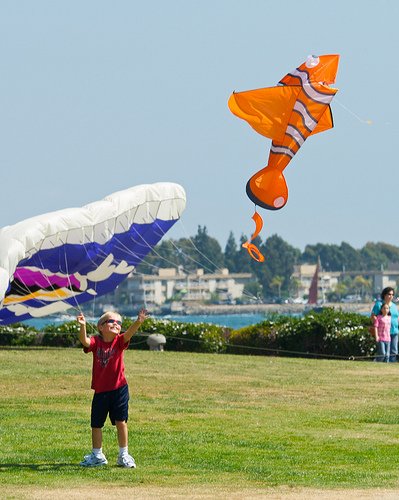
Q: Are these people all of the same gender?
A: No, they are both male and female.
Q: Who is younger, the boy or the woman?
A: The boy is younger than the woman.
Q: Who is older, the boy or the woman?
A: The woman is older than the boy.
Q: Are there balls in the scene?
A: No, there are no balls.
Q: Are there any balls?
A: No, there are no balls.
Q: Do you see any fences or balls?
A: No, there are no balls or fences.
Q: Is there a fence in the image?
A: No, there are no fences.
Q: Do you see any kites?
A: Yes, there is a kite.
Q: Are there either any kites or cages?
A: Yes, there is a kite.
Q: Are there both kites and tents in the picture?
A: No, there is a kite but no tents.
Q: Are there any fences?
A: No, there are no fences.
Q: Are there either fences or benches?
A: No, there are no fences or benches.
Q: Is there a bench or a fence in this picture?
A: No, there are no fences or benches.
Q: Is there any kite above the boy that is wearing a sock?
A: Yes, there is a kite above the boy.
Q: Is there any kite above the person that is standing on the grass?
A: Yes, there is a kite above the boy.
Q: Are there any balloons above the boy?
A: No, there is a kite above the boy.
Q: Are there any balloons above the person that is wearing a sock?
A: No, there is a kite above the boy.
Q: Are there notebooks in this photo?
A: No, there are no notebooks.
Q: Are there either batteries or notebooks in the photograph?
A: No, there are no notebooks or batteries.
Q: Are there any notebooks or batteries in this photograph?
A: No, there are no notebooks or batteries.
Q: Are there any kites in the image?
A: Yes, there is a kite.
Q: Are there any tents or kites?
A: Yes, there is a kite.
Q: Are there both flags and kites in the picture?
A: No, there is a kite but no flags.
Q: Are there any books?
A: No, there are no books.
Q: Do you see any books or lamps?
A: No, there are no books or lamps.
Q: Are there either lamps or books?
A: No, there are no books or lamps.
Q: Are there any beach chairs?
A: No, there are no beach chairs.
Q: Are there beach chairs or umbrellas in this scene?
A: No, there are no beach chairs or umbrellas.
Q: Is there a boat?
A: Yes, there is a boat.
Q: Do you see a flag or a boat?
A: Yes, there is a boat.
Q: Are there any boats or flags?
A: Yes, there is a boat.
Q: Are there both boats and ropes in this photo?
A: No, there is a boat but no ropes.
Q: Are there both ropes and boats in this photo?
A: No, there is a boat but no ropes.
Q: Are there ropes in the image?
A: No, there are no ropes.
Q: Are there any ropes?
A: No, there are no ropes.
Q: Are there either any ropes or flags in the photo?
A: No, there are no ropes or flags.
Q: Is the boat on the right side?
A: Yes, the boat is on the right of the image.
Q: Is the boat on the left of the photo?
A: No, the boat is on the right of the image.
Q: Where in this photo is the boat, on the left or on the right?
A: The boat is on the right of the image.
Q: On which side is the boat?
A: The boat is on the right of the image.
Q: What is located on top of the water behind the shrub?
A: The boat is on top of the water.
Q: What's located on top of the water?
A: The boat is on top of the water.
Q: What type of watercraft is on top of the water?
A: The watercraft is a boat.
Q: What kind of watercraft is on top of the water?
A: The watercraft is a boat.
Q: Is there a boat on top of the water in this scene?
A: Yes, there is a boat on top of the water.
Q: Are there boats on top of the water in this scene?
A: Yes, there is a boat on top of the water.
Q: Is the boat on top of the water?
A: Yes, the boat is on top of the water.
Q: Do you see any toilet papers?
A: No, there are no toilet papers.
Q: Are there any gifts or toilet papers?
A: No, there are no toilet papers or gifts.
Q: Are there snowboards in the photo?
A: No, there are no snowboards.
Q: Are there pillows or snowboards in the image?
A: No, there are no snowboards or pillows.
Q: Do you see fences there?
A: No, there are no fences.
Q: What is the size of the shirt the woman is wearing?
A: The shirt is large.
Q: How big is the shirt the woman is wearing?
A: The shirt is large.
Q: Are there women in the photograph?
A: Yes, there is a woman.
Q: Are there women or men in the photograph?
A: Yes, there is a woman.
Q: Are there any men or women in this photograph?
A: Yes, there is a woman.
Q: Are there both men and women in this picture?
A: No, there is a woman but no men.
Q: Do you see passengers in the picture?
A: No, there are no passengers.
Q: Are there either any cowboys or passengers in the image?
A: No, there are no passengers or cowboys.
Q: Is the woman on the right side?
A: Yes, the woman is on the right of the image.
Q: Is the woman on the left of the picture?
A: No, the woman is on the right of the image.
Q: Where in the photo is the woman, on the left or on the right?
A: The woman is on the right of the image.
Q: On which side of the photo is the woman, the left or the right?
A: The woman is on the right of the image.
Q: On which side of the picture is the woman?
A: The woman is on the right of the image.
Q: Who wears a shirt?
A: The woman wears a shirt.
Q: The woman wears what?
A: The woman wears a shirt.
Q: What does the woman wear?
A: The woman wears a shirt.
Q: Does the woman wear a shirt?
A: Yes, the woman wears a shirt.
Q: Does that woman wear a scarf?
A: No, the woman wears a shirt.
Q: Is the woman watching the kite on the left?
A: Yes, the woman is watching the kite.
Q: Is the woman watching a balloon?
A: No, the woman is watching the kite.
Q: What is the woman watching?
A: The woman is watching the kite.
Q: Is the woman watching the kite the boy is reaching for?
A: Yes, the woman is watching the kite.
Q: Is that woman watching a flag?
A: No, the woman is watching the kite.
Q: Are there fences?
A: No, there are no fences.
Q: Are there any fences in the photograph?
A: No, there are no fences.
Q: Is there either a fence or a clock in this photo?
A: No, there are no fences or clocks.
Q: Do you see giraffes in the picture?
A: No, there are no giraffes.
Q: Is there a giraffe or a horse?
A: No, there are no giraffes or horses.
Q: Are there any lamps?
A: No, there are no lamps.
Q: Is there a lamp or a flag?
A: No, there are no lamps or flags.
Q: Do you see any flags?
A: No, there are no flags.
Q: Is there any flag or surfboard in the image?
A: No, there are no flags or surfboards.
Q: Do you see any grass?
A: Yes, there is grass.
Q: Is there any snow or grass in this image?
A: Yes, there is grass.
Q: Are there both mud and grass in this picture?
A: No, there is grass but no mud.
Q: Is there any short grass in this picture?
A: Yes, there is short grass.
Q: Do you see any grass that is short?
A: Yes, there is grass that is short.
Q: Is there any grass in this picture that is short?
A: Yes, there is grass that is short.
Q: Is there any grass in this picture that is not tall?
A: Yes, there is short grass.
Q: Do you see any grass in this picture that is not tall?
A: Yes, there is short grass.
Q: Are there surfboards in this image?
A: No, there are no surfboards.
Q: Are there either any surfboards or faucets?
A: No, there are no surfboards or faucets.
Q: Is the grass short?
A: Yes, the grass is short.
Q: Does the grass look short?
A: Yes, the grass is short.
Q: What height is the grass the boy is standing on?
A: The grass is short.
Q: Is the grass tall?
A: No, the grass is short.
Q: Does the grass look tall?
A: No, the grass is short.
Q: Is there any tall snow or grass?
A: No, there is grass but it is short.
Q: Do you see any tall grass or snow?
A: No, there is grass but it is short.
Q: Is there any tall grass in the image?
A: No, there is grass but it is short.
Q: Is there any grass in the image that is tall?
A: No, there is grass but it is short.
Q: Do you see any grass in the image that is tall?
A: No, there is grass but it is short.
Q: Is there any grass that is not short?
A: No, there is grass but it is short.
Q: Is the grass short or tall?
A: The grass is short.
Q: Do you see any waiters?
A: No, there are no waiters.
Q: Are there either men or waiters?
A: No, there are no waiters or men.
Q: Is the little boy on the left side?
A: Yes, the boy is on the left of the image.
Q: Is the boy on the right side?
A: No, the boy is on the left of the image.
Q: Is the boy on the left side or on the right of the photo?
A: The boy is on the left of the image.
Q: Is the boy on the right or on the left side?
A: The boy is on the left of the image.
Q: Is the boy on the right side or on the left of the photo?
A: The boy is on the left of the image.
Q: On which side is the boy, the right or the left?
A: The boy is on the left of the image.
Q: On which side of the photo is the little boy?
A: The boy is on the left of the image.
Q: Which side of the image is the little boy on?
A: The boy is on the left of the image.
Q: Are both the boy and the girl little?
A: Yes, both the boy and the girl are little.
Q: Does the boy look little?
A: Yes, the boy is little.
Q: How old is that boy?
A: The boy is little.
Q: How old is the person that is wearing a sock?
A: The boy is little.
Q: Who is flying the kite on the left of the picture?
A: The boy is flying the kite.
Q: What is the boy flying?
A: The boy is flying the kite.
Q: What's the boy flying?
A: The boy is flying the kite.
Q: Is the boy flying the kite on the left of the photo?
A: Yes, the boy is flying the kite.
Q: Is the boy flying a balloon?
A: No, the boy is flying the kite.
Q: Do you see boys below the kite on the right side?
A: Yes, there is a boy below the kite.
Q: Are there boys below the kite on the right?
A: Yes, there is a boy below the kite.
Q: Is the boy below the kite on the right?
A: Yes, the boy is below the kite.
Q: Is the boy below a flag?
A: No, the boy is below the kite.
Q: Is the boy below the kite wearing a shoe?
A: Yes, the boy is wearing a shoe.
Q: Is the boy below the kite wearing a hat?
A: No, the boy is wearing a shoe.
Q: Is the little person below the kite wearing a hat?
A: No, the boy is wearing a shoe.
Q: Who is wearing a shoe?
A: The boy is wearing a shoe.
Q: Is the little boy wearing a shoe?
A: Yes, the boy is wearing a shoe.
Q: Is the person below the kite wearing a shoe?
A: Yes, the boy is wearing a shoe.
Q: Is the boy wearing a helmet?
A: No, the boy is wearing a shoe.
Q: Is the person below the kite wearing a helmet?
A: No, the boy is wearing a shoe.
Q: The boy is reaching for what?
A: The boy is reaching for the kite.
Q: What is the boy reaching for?
A: The boy is reaching for the kite.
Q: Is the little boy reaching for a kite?
A: Yes, the boy is reaching for a kite.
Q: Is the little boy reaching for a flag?
A: No, the boy is reaching for a kite.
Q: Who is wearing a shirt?
A: The boy is wearing a shirt.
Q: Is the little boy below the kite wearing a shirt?
A: Yes, the boy is wearing a shirt.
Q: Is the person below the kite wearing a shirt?
A: Yes, the boy is wearing a shirt.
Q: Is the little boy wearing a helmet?
A: No, the boy is wearing a shirt.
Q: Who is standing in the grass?
A: The boy is standing in the grass.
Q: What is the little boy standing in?
A: The boy is standing in the grass.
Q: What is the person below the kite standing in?
A: The boy is standing in the grass.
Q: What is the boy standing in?
A: The boy is standing in the grass.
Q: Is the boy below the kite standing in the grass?
A: Yes, the boy is standing in the grass.